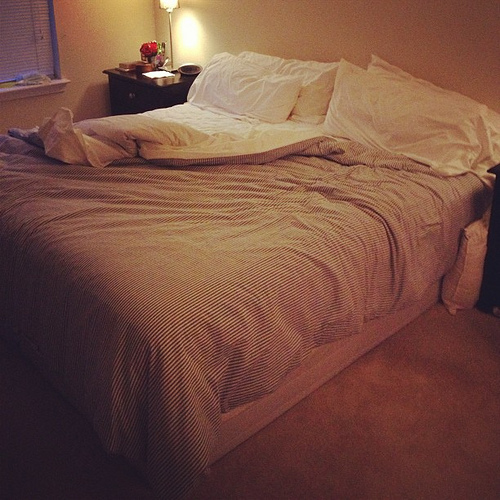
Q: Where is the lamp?
A: On the nightstand.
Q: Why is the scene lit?
A: The lamp is on.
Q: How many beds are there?
A: One.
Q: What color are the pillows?
A: White.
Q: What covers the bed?
A: A bedspread.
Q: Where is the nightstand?
A: In the corner.